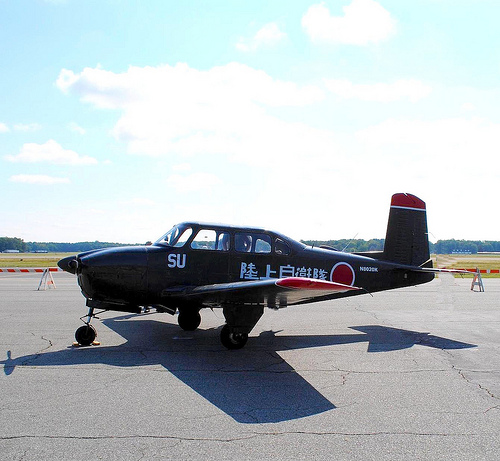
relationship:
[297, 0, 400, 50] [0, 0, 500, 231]
cloud in blue sky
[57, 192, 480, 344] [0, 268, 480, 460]
plane on tarmac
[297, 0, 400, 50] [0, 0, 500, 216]
cloud in blue sky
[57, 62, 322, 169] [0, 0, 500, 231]
cloud in blue sky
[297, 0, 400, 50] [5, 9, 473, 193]
cloud in sky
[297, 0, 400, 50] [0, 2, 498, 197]
cloud in sky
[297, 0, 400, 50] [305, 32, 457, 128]
cloud in sky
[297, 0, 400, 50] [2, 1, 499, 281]
cloud in sky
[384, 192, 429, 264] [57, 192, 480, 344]
tail of plane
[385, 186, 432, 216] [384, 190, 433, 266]
red tip of tail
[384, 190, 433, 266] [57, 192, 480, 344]
tail of plane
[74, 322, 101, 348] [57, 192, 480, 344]
landing gear of plane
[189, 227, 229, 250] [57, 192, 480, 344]
window on plane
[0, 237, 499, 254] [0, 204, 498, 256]
tree tops on horizon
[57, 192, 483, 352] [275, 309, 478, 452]
plane parked on tarmac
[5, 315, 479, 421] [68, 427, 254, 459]
shadow on cement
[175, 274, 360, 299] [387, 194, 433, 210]
wing with red tip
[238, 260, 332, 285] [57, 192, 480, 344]
characters on plane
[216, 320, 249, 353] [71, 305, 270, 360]
wheel on landing gear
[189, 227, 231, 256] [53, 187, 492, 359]
window on plane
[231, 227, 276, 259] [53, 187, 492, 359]
plane window on plane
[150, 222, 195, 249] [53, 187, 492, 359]
plane window on plane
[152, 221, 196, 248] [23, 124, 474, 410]
plane window on plane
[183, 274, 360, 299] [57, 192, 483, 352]
wing on plane